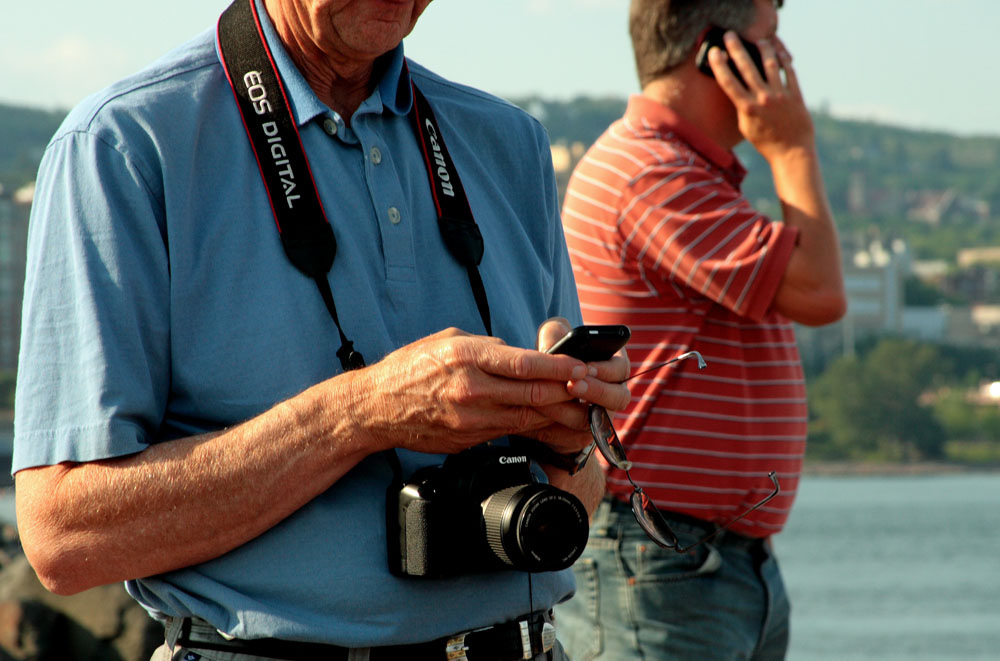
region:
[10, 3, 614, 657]
Man wearing a blue polo shirt.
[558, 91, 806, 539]
Red shirt with white stripes.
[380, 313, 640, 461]
Two hands holding a cellphone.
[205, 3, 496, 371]
Black camera strap hanging around neck.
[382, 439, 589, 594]
Black camera with a large lens.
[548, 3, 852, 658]
Man talking on a cellphone.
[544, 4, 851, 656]
Man wearing blue jeans.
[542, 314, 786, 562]
Left hand holding glasses.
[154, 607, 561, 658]
Black belt with a silver buckle.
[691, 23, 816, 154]
Right hand holding a cellphone.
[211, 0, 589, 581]
a black camera with a black strap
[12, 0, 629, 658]
man in blue shirt holding a cellphone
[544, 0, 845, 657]
man wearing blue jeans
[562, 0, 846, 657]
man holding a cellphone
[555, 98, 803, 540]
a red shirt with white lines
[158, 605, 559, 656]
a black and metal belt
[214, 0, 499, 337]
a black strap with red borders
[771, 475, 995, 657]
a blue calm river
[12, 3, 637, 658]
man wearing blue polo shirt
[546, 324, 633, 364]
black cellphone with silver button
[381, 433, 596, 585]
black cannon camera hanging from man's neck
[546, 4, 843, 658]
man in blue jeans talking on black cellphone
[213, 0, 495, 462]
black, white and red camera strap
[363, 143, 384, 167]
round white pearl button on blue shirt collar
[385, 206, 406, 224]
round white pearl button on blue shirt collar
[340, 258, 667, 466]
the man is holding the phone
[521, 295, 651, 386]
the phone is black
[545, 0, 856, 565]
the man is wearing a striped shirt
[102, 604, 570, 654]
the man is wearing a belt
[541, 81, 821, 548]
the shirt is red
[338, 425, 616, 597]
the camera is black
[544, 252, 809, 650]
the man is wearing jeans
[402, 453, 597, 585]
a camera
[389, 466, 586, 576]
a black camera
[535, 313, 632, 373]
a cellphone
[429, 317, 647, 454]
person holding a cellphone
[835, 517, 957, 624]
the water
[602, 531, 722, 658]
man is wearing pants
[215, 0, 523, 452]
neck strap for camera with EOS DIGITAL on it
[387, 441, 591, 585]
cannon high end digital camera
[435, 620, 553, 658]
silver belt buckle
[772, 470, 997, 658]
calm blue lake or sea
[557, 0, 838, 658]
man in red stripped shirt talking on phone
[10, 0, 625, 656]
man in blue shirt texting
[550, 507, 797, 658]
blue jeans worn with shirt tucked in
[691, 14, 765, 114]
black cel phone held to mans ear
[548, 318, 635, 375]
black cel phone held by older man in two hands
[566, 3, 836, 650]
A man talking on a cellphone.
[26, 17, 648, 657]
A person with a cell phone in their hands.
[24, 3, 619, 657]
A person with a pair of sunglasses in their hands.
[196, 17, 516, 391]
A black, red, and white camera strap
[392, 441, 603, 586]
A black camera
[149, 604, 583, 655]
A black belt.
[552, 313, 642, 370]
A black cellphone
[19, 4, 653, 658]
A person with a camera around their neck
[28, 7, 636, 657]
A person wearing a black belt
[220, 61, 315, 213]
EOS DIGITAL is written in white on a black carrying strap.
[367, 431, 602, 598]
A black camera is visible and it says Canon in white.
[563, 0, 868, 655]
A man is talking on a black cell phone.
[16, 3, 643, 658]
A man is looking down at his black cell phone.